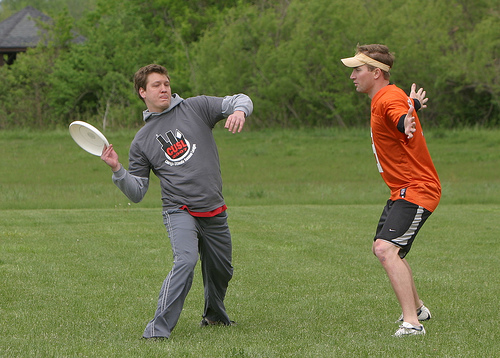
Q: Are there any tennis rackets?
A: No, there are no tennis rackets.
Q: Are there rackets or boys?
A: No, there are no rackets or boys.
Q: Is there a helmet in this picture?
A: No, there are no helmets.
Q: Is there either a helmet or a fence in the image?
A: No, there are no helmets or fences.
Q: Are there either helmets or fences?
A: No, there are no helmets or fences.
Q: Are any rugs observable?
A: No, there are no rugs.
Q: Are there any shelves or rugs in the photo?
A: No, there are no rugs or shelves.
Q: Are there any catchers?
A: No, there are no catchers.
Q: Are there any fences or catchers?
A: No, there are no catchers or fences.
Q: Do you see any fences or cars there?
A: No, there are no fences or cars.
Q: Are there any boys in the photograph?
A: No, there are no boys.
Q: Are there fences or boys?
A: No, there are no boys or fences.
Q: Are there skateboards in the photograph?
A: No, there are no skateboards.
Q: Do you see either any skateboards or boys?
A: No, there are no skateboards or boys.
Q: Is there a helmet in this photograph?
A: No, there are no helmets.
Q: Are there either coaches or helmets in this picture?
A: No, there are no helmets or coaches.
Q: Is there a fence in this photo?
A: No, there are no fences.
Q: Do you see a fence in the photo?
A: No, there are no fences.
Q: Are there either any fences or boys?
A: No, there are no fences or boys.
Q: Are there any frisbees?
A: Yes, there is a frisbee.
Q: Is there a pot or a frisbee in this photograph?
A: Yes, there is a frisbee.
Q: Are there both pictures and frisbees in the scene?
A: Yes, there are both a frisbee and a picture.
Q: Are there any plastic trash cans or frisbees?
A: Yes, there is a plastic frisbee.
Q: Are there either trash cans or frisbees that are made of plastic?
A: Yes, the frisbee is made of plastic.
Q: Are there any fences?
A: No, there are no fences.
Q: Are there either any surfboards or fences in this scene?
A: No, there are no fences or surfboards.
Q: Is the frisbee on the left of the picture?
A: Yes, the frisbee is on the left of the image.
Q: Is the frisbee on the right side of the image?
A: No, the frisbee is on the left of the image.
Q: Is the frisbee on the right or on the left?
A: The frisbee is on the left of the image.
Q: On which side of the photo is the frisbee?
A: The frisbee is on the left of the image.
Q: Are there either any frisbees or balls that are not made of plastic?
A: No, there is a frisbee but it is made of plastic.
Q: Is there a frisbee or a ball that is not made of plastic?
A: No, there is a frisbee but it is made of plastic.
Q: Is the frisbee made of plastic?
A: Yes, the frisbee is made of plastic.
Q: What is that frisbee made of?
A: The frisbee is made of plastic.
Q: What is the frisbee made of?
A: The frisbee is made of plastic.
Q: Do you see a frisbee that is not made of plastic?
A: No, there is a frisbee but it is made of plastic.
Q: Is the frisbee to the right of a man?
A: No, the frisbee is to the left of a man.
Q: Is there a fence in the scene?
A: No, there are no fences.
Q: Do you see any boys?
A: No, there are no boys.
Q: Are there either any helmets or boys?
A: No, there are no boys or helmets.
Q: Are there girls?
A: No, there are no girls.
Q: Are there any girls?
A: No, there are no girls.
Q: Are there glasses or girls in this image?
A: No, there are no girls or glasses.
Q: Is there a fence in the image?
A: No, there are no fences.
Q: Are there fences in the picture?
A: No, there are no fences.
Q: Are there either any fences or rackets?
A: No, there are no fences or rackets.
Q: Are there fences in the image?
A: No, there are no fences.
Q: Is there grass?
A: Yes, there is grass.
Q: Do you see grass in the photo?
A: Yes, there is grass.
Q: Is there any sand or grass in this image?
A: Yes, there is grass.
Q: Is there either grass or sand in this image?
A: Yes, there is grass.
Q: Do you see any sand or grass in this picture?
A: Yes, there is grass.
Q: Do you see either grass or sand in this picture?
A: Yes, there is grass.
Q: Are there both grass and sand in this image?
A: No, there is grass but no sand.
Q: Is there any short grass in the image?
A: Yes, there is short grass.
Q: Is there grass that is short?
A: Yes, there is grass that is short.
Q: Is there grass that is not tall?
A: Yes, there is short grass.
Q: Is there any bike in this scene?
A: No, there are no bikes.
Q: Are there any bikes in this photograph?
A: No, there are no bikes.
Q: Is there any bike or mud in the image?
A: No, there are no bikes or mud.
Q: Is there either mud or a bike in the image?
A: No, there are no bikes or mud.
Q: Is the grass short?
A: Yes, the grass is short.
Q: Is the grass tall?
A: No, the grass is short.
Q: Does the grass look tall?
A: No, the grass is short.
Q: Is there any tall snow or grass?
A: No, there is grass but it is short.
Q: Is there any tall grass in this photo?
A: No, there is grass but it is short.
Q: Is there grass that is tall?
A: No, there is grass but it is short.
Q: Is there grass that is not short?
A: No, there is grass but it is short.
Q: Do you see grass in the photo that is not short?
A: No, there is grass but it is short.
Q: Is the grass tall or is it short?
A: The grass is short.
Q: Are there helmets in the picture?
A: No, there are no helmets.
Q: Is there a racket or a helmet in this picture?
A: No, there are no helmets or rackets.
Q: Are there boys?
A: No, there are no boys.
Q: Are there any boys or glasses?
A: No, there are no boys or glasses.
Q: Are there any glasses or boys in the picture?
A: No, there are no boys or glasses.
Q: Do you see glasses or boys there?
A: No, there are no boys or glasses.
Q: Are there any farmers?
A: No, there are no farmers.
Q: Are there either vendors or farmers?
A: No, there are no farmers or vendors.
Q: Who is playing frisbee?
A: The man is playing frisbee.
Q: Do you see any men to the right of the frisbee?
A: Yes, there is a man to the right of the frisbee.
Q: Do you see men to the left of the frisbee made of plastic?
A: No, the man is to the right of the frisbee.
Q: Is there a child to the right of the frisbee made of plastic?
A: No, there is a man to the right of the frisbee.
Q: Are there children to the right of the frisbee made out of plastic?
A: No, there is a man to the right of the frisbee.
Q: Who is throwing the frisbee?
A: The man is throwing the frisbee.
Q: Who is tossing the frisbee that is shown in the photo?
A: The man is tossing the frisbee.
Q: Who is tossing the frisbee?
A: The man is tossing the frisbee.